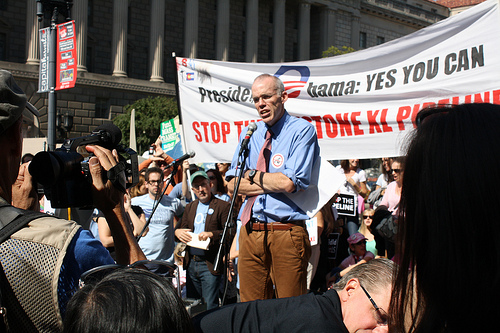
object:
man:
[227, 74, 321, 302]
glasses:
[250, 94, 269, 100]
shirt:
[233, 110, 323, 216]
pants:
[236, 222, 307, 296]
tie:
[240, 135, 270, 223]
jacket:
[177, 200, 235, 253]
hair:
[279, 83, 282, 93]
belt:
[245, 221, 299, 236]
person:
[384, 164, 406, 215]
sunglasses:
[391, 167, 402, 173]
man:
[129, 166, 180, 270]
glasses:
[147, 178, 164, 183]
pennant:
[38, 25, 49, 93]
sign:
[170, 1, 498, 162]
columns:
[298, 3, 313, 60]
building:
[9, 2, 439, 152]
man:
[175, 176, 236, 306]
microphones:
[206, 123, 254, 270]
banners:
[55, 20, 80, 89]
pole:
[45, 91, 56, 149]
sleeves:
[282, 130, 315, 184]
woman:
[404, 110, 500, 324]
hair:
[401, 113, 499, 326]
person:
[4, 67, 127, 326]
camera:
[31, 123, 137, 207]